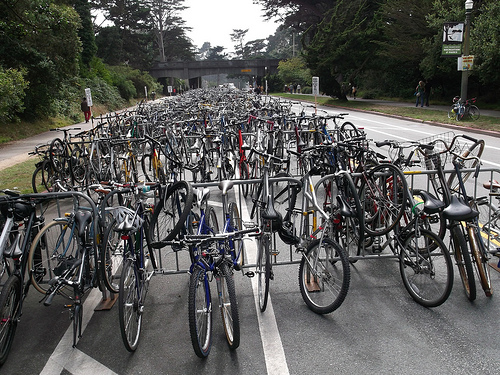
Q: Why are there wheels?
A: For the bikes.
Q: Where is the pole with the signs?
A: Right side of street.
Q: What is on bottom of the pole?
A: Bikes.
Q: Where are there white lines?
A: Street.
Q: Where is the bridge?
A: Over the street in the background.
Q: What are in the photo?
A: Bicycles.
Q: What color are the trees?
A: Green.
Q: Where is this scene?
A: Road.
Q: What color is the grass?
A: Green.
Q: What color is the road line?
A: White.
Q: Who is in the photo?
A: No one.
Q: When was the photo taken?
A: Daytime.